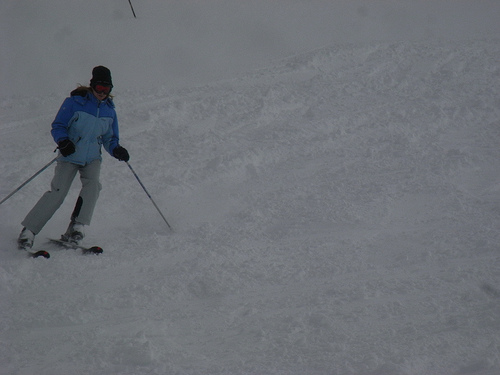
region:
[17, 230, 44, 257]
the woman is wearing snow boots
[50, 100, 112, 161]
the woman is wearing a blue coat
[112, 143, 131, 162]
woman in black gloves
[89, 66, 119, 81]
woman is wearing a black beanie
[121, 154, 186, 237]
woman is carrying a ski pole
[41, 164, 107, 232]
woman is wearing grey pants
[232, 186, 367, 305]
snow is on the ground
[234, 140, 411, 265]
snow covers the ground and surrounding area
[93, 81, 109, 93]
red goggles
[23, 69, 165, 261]
a woman is skiing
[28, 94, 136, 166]
a blue jacket on person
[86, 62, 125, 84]
black hat on person's head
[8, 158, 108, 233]
white snow pants on person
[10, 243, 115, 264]
black top of snow skis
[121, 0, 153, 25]
a piece of a ski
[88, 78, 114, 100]
gloggles on a person's face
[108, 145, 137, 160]
black glove on hand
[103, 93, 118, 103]
a piece of brown hair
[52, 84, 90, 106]
a black hood on jacket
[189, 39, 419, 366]
a lot of snow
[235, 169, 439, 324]
the snow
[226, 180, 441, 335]
the snow is white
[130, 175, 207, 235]
a ski pole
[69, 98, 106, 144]
a blue jacket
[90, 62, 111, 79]
person wearing a beanie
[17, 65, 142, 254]
person is skiing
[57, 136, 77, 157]
gloves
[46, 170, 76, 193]
grey pants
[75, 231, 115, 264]
the person is wearing skiis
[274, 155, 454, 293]
the snow is white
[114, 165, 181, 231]
ski pole in the photo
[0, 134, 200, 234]
two ski poles in lady's hands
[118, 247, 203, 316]
snow under the lady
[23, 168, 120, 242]
pants of the lady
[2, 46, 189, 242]
lady in a blue outfit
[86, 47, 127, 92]
hat on lady's head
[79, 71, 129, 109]
goggles on lady's face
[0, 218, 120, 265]
skis on the ground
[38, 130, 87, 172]
glove on woman's hand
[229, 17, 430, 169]
snow in the background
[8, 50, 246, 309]
woman skiing in snow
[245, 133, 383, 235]
area of white snow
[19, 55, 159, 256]
woman wearing skiing gear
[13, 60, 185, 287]
woman on skiis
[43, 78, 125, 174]
woman wearing a jacket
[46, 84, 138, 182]
woman wearing a blue jacket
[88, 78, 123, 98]
woman wearing snow goggles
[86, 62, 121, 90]
woman wearing a beanie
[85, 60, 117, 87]
woman wearing a black benie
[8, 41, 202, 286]
woman using skiing equipment